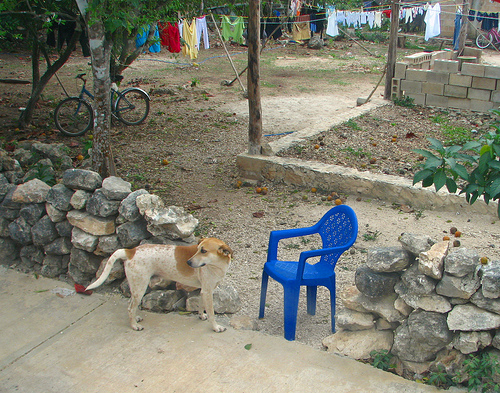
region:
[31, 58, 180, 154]
bike on the ground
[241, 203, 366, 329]
blue chair on the ground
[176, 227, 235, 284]
head of the dog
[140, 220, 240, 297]
brown and white dog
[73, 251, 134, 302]
tail of the dog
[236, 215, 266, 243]
rocks on the ground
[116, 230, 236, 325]
dog looking behind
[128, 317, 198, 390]
cement under the dog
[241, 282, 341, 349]
legs of the chair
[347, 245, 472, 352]
rock fence near the dog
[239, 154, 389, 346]
a bright blue chair is in a yard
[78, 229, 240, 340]
a dog is standing in the yard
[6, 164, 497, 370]
rock walls are next to a patio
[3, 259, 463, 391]
the patio is poured cement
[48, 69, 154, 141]
a bike is leaning against a tree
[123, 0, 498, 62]
a clothes line is in the yard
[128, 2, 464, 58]
clothes are drying on the clothes line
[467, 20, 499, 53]
a bike is leaning against a house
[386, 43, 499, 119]
cement blocks are stacked on each other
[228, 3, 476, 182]
wood poles are set in cement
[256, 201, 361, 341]
A blue plastic chair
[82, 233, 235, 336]
The dog is white and brown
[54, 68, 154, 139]
A bicycle with two wheels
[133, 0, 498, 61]
Laundry is hanging on a line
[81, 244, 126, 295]
White tail of a dog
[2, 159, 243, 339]
Large gray rocks behind the dog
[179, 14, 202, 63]
A clothing garment is yellow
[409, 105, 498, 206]
Green leaves on a tree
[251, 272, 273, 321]
A leg of a chair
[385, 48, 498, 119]
Large blocks made of cement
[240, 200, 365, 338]
blue plastic chair on ground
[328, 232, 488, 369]
stone wall by patio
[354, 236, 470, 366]
stones stacked on each other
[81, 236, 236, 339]
dog standing on sidewalk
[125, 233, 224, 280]
brown and white dog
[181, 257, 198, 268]
black nose of dog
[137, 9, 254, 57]
clothes hanging from line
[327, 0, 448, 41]
white clothes hanging down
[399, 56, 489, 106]
stacked up cinder blocks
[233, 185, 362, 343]
blue plastic chair in the dirt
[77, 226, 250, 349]
dog standing on side walk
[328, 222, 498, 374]
stone wall by sidewalk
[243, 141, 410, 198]
concrete curbing of a garden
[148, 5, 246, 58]
clothes drying on a line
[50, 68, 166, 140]
bike in the dirt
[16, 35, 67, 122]
trunk of a tree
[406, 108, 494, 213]
green leaves of a tree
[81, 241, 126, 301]
tail of a dog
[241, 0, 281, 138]
wooden pole in dirt ground